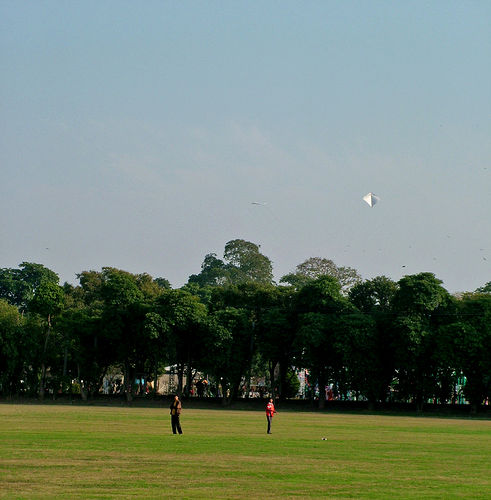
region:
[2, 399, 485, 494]
flat ground with loose rows of grass and dirt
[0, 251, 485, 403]
low wall and trees at end of lawn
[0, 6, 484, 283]
clear sky over trees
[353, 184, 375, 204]
kite in the shape of white diamond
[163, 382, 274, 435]
people standing apart with backs toward each other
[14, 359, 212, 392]
white buildings seen through trees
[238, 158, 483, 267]
smaller objects in sky near kite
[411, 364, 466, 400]
house with shutters on other side of trees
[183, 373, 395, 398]
colorful shapes seen through trees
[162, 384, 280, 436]
sun shining on people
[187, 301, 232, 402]
tree along the side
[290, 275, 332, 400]
tree along the side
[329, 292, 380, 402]
tree along the side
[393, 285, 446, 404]
tree along the side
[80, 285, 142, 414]
tree along the side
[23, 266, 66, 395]
tree along the side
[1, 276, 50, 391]
tree along the side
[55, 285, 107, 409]
tree along the side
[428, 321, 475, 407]
tree along the side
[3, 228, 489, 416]
Group of trees in the distance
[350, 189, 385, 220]
White kite in the sky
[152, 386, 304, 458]
Two people in the field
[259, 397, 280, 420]
Red jacket on person flying a kite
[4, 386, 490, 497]
Field of green grass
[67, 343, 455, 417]
Buildings behind the trees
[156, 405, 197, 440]
Black pants on a person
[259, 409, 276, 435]
Blue jeans on a person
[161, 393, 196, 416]
Brown jacket on a person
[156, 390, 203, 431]
Person looking to the left